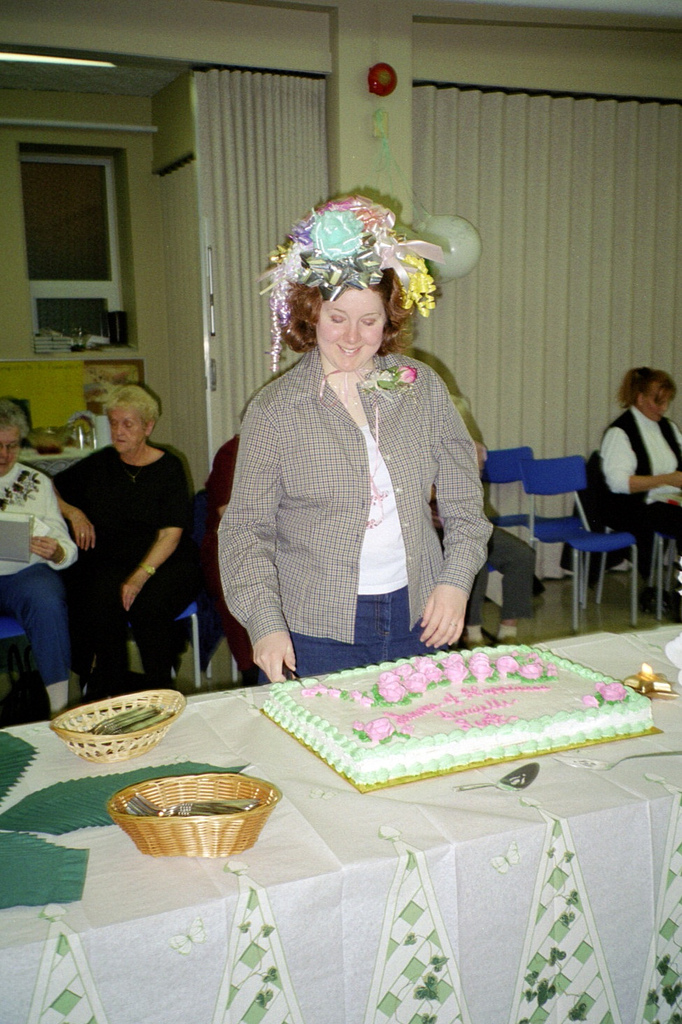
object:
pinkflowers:
[363, 715, 394, 743]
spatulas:
[452, 762, 540, 794]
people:
[218, 184, 494, 683]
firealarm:
[368, 61, 397, 96]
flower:
[362, 365, 418, 393]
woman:
[597, 364, 682, 613]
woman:
[52, 381, 190, 702]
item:
[623, 663, 680, 702]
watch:
[138, 561, 155, 575]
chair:
[518, 455, 637, 635]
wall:
[410, 20, 682, 103]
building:
[0, 0, 682, 1022]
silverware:
[126, 792, 262, 814]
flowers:
[377, 652, 495, 704]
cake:
[263, 644, 653, 786]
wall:
[331, 0, 413, 221]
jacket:
[217, 347, 494, 649]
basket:
[106, 772, 283, 859]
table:
[0, 624, 682, 1023]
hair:
[258, 192, 443, 357]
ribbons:
[326, 195, 447, 291]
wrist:
[125, 555, 156, 590]